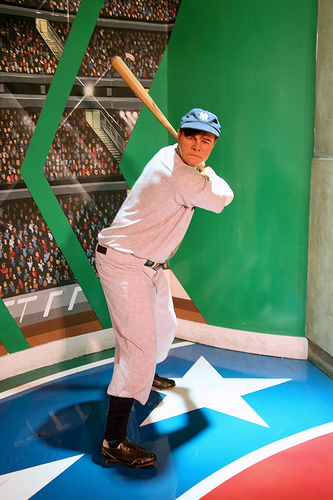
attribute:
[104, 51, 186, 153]
bat — wooden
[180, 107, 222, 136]
cap — blue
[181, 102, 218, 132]
cap — blue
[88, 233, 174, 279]
belt — black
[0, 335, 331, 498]
floor — painted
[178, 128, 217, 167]
face — wax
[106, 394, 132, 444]
sock — black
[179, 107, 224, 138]
hat — New York, blue, baseball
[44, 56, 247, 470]
statue — wax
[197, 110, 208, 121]
logo — white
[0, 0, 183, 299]
backdrop — painted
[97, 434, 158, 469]
shoe — dark colored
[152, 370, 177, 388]
shoe — dark colored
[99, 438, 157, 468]
cleats — black, leather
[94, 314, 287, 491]
star — white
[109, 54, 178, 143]
bat — wooden 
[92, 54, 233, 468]
wax figure — lifelike 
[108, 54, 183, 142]
baseball bat — wooden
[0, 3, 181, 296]
illustration — colorful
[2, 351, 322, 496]
background — blue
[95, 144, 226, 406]
uniform — white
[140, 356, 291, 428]
star — white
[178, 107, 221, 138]
cap — blue, baseball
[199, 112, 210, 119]
logo — white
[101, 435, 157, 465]
cleat — black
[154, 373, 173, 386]
cleat — black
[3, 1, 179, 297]
picture — fans in stands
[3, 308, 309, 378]
base — wood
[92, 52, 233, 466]
figure — wax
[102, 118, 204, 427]
statue — wax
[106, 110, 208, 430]
statue — life-sized, wax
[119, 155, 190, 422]
uniform — white